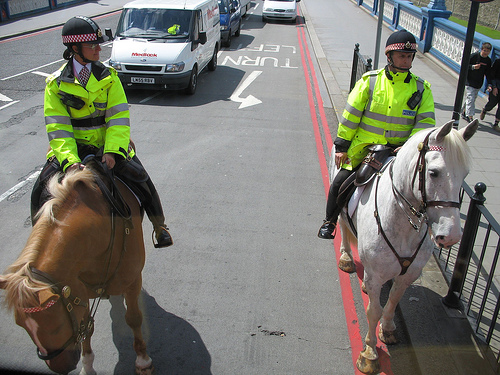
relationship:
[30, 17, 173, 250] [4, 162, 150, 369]
police officer riding horse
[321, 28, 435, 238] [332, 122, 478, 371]
police officer riding horse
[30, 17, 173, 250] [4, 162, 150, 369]
police officer on horse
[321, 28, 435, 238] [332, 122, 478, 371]
police officer on horse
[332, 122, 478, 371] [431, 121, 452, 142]
horse has ear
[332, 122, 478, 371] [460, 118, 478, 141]
horse has ear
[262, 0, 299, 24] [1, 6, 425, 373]
car on ground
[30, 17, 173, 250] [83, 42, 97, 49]
police officer wearing eye glasses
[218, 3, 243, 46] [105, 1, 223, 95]
car behind van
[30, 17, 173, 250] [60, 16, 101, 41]
police officer wearing helmet